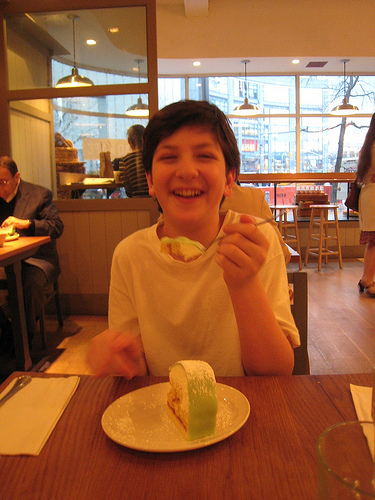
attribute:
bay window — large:
[163, 71, 357, 172]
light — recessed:
[85, 38, 96, 47]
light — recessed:
[190, 60, 201, 66]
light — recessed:
[291, 59, 301, 65]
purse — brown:
[342, 178, 365, 216]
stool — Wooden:
[268, 202, 301, 272]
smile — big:
[162, 180, 210, 204]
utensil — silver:
[1, 373, 32, 407]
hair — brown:
[141, 100, 239, 174]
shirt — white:
[101, 212, 302, 380]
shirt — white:
[113, 208, 301, 376]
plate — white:
[106, 376, 260, 453]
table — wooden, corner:
[0, 369, 373, 497]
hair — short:
[155, 102, 279, 153]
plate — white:
[98, 380, 250, 453]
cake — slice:
[165, 356, 219, 441]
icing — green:
[169, 360, 215, 437]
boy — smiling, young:
[89, 97, 313, 381]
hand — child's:
[213, 214, 269, 282]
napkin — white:
[0, 373, 85, 459]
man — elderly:
[0, 164, 75, 322]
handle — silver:
[7, 365, 32, 392]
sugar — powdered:
[95, 381, 180, 455]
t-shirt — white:
[95, 203, 303, 391]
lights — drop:
[37, 80, 347, 119]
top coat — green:
[173, 358, 215, 441]